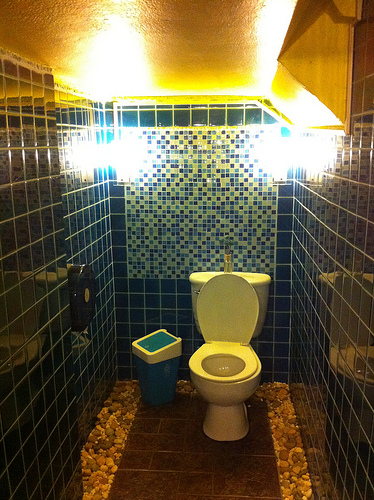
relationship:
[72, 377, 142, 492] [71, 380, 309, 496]
rocks are on ground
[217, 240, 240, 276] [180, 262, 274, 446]
bottle on toilet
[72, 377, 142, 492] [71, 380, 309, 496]
rocks on ground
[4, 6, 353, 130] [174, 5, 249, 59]
ceiling has popcorn surace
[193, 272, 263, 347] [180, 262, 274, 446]
lid on toilet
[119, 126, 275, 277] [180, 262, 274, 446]
tiles are behind toilet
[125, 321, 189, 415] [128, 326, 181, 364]
trash can has white lid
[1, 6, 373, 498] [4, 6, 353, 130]
bathroom has ceiling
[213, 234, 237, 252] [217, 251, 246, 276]
plant in vase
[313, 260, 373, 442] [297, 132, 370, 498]
reflection on wall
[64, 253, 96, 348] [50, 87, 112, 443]
dispenser on wall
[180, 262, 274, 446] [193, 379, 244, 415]
toilet has decoration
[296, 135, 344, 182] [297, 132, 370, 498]
reflection on wall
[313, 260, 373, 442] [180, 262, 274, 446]
reflection of toilet